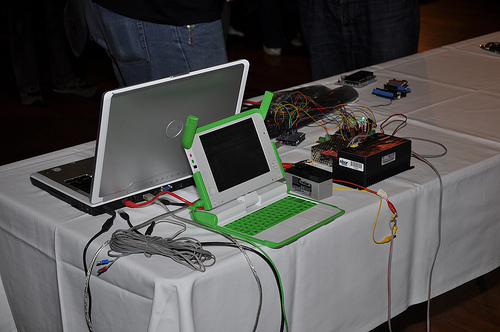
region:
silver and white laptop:
[50, 60, 245, 220]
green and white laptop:
[182, 90, 336, 242]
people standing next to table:
[83, 4, 415, 96]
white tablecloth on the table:
[5, 44, 497, 330]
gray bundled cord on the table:
[104, 216, 219, 277]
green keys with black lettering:
[234, 191, 309, 238]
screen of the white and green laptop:
[197, 114, 265, 189]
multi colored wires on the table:
[262, 76, 455, 187]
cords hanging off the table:
[43, 179, 457, 330]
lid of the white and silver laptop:
[100, 72, 247, 187]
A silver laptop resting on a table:
[30, 57, 250, 213]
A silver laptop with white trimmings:
[30, 56, 250, 212]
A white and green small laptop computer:
[180, 90, 345, 248]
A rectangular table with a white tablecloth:
[2, 28, 499, 329]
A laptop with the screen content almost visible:
[180, 90, 346, 250]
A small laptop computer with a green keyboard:
[180, 89, 345, 249]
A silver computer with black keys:
[30, 58, 250, 215]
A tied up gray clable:
[95, 217, 216, 282]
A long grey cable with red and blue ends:
[96, 228, 216, 278]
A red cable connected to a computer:
[121, 188, 192, 206]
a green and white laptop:
[140, 79, 376, 278]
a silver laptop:
[22, 64, 233, 210]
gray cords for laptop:
[95, 199, 217, 292]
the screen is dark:
[190, 129, 272, 190]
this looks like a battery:
[281, 143, 336, 215]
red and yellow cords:
[350, 179, 413, 258]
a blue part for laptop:
[351, 66, 420, 111]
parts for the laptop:
[295, 105, 436, 187]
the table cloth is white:
[412, 64, 499, 135]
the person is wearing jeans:
[105, 1, 235, 81]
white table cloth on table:
[75, 16, 495, 315]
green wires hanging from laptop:
[227, 240, 309, 312]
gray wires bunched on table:
[113, 211, 230, 277]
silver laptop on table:
[82, 97, 228, 209]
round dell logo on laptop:
[163, 105, 192, 150]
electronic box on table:
[310, 111, 401, 177]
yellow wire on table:
[366, 203, 399, 252]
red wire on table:
[327, 178, 380, 201]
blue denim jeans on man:
[113, 29, 232, 98]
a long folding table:
[0, 30, 498, 330]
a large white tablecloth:
[0, 30, 499, 330]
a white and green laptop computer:
[181, 90, 345, 247]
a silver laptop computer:
[30, 58, 249, 216]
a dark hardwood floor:
[368, 0, 498, 330]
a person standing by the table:
[296, 0, 420, 81]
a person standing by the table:
[83, 0, 226, 88]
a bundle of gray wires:
[95, 217, 215, 272]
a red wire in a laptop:
[120, 189, 204, 209]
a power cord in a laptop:
[82, 203, 114, 330]